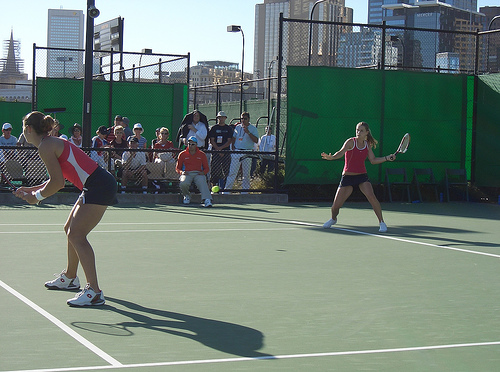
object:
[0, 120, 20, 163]
woman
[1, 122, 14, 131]
cap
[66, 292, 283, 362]
shadow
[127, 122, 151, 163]
woman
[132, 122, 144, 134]
hat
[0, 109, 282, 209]
audience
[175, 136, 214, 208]
man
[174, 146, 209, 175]
pull-over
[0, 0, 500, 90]
sky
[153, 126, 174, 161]
spectator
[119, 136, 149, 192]
spectator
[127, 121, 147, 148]
spectator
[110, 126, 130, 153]
spectator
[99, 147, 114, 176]
spectator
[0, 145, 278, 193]
fence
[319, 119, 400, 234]
player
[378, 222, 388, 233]
shoe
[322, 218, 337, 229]
shoe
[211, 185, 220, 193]
ball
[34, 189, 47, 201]
wristband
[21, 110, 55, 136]
hair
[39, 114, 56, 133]
bun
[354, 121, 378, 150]
hair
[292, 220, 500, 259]
white lines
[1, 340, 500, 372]
white lines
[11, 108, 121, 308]
players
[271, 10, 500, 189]
fence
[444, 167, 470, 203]
chair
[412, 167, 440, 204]
chair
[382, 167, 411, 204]
chair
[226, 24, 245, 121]
pole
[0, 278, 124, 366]
white lines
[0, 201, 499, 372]
court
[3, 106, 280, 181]
spectators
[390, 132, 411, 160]
racket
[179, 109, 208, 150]
man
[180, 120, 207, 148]
shirt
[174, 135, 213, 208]
coach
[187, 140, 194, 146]
sunglasses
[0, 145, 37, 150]
sidelines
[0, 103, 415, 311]
game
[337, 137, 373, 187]
uniform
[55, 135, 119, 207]
uniform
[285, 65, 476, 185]
mesh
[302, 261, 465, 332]
sun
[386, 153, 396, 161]
hand